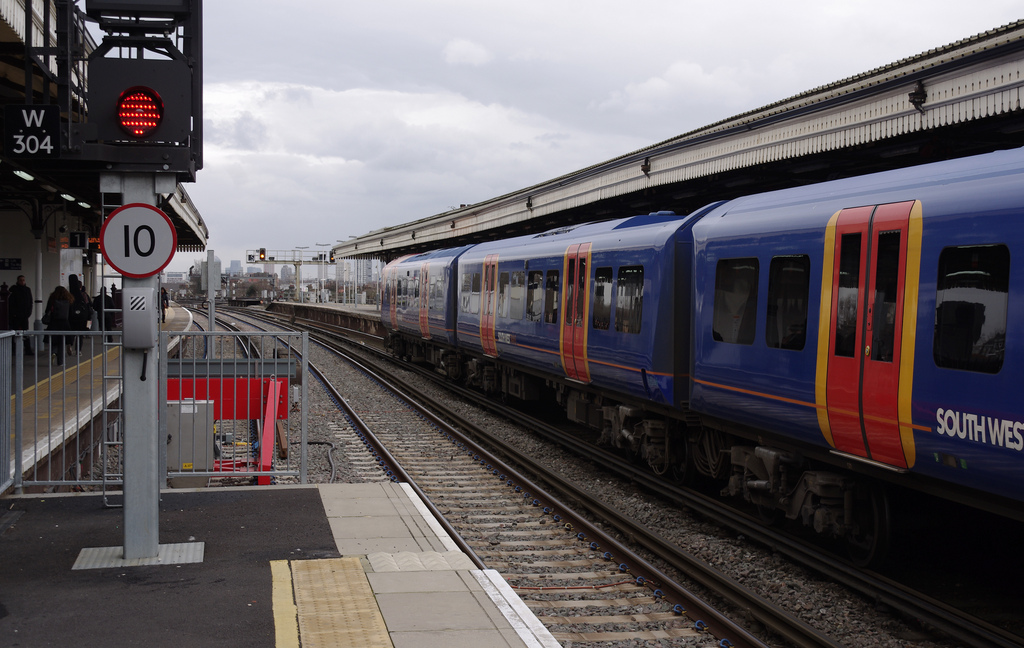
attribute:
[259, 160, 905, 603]
train — blue , red , yellow 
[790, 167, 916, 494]
doors — red 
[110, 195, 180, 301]
numbers — black 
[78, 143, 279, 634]
sign — white 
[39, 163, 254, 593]
post — gray 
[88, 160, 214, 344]
sign — white , Round 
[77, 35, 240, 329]
sign — Black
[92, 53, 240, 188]
light — red 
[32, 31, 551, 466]
light — yellow 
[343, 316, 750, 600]
track — Empty , metal 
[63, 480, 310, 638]
platform — black, gray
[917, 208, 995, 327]
window — glass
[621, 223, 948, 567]
train — blue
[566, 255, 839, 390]
train — blue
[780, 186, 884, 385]
window — glass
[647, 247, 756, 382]
window — glass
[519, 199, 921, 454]
train — blue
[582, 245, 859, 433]
train — blue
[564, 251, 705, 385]
window — glass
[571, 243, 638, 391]
window — glass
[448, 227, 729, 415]
train — blue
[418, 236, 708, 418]
train — blue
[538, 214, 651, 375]
window — glass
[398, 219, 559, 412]
window — glass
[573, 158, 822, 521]
train — blue